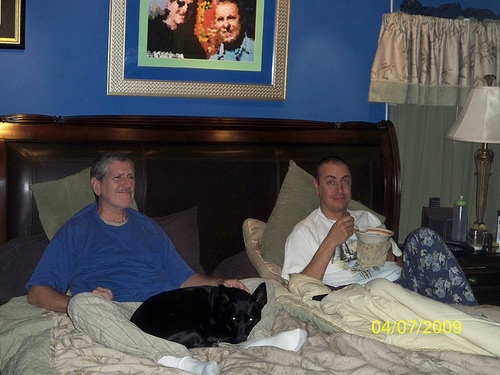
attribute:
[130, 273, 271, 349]
dog — black, black in color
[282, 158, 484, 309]
man — eating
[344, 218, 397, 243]
bowl — beige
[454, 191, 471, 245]
bottle — plastic, green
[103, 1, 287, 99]
picture — framed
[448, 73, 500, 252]
lamp — tall, white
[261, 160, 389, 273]
cushion — green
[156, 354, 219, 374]
sock — white, white colored, white in color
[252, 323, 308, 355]
sock — white, white colored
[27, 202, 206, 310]
shirt — blue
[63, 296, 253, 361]
pants — tan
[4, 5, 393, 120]
wall — blue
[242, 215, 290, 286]
pillow — tan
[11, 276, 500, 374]
comforter — tan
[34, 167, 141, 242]
pillow — green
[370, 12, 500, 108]
curtain — beige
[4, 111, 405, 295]
headboard — brown